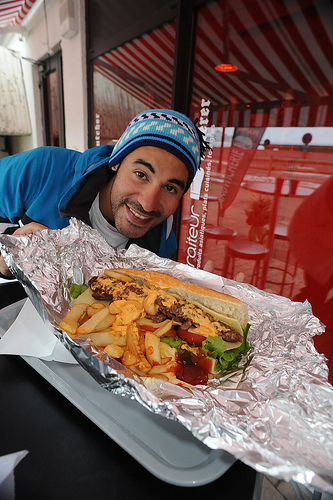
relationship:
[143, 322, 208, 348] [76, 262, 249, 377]
tomatoes on sandwich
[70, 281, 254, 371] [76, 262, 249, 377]
lettuce on sandwich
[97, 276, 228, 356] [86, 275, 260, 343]
cheese on meat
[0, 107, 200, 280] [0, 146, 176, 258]
man has jacket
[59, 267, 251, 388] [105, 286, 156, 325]
burger with cheese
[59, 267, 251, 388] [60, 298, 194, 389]
burger with french fries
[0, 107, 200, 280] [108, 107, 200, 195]
man wearing a beanie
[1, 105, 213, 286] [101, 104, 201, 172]
man wearing a hat